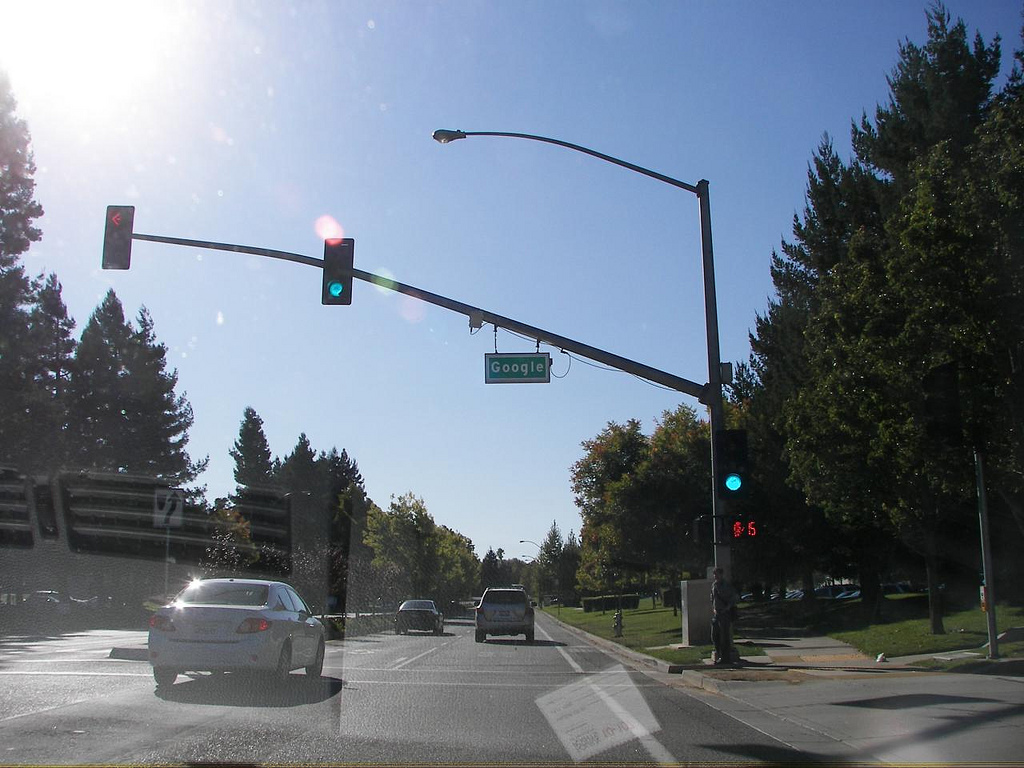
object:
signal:
[101, 203, 137, 268]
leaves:
[635, 455, 662, 477]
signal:
[720, 510, 769, 547]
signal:
[321, 237, 356, 306]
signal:
[714, 428, 750, 498]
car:
[157, 574, 336, 680]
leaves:
[921, 197, 942, 214]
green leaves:
[841, 284, 892, 324]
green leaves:
[796, 362, 846, 395]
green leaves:
[629, 493, 662, 516]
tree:
[592, 399, 736, 581]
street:
[11, 604, 687, 761]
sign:
[482, 351, 552, 386]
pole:
[699, 401, 746, 668]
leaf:
[955, 69, 968, 74]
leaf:
[891, 193, 910, 208]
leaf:
[933, 151, 957, 171]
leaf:
[904, 219, 928, 238]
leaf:
[821, 289, 841, 309]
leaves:
[857, 455, 890, 481]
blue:
[644, 47, 760, 126]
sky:
[23, 10, 754, 472]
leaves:
[990, 129, 1019, 150]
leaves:
[833, 302, 865, 328]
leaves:
[970, 325, 1003, 350]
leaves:
[390, 528, 411, 544]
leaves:
[605, 447, 630, 472]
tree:
[577, 417, 651, 500]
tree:
[377, 494, 438, 602]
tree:
[68, 293, 192, 528]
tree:
[207, 397, 276, 602]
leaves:
[801, 304, 829, 325]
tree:
[803, 83, 1024, 630]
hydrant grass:
[612, 607, 626, 637]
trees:
[5, 258, 74, 467]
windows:
[278, 588, 311, 614]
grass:
[565, 590, 999, 647]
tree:
[525, 519, 568, 611]